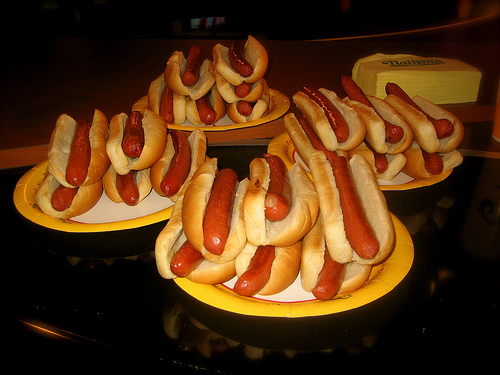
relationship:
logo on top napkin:
[373, 50, 449, 69] [349, 38, 483, 105]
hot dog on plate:
[155, 150, 395, 300] [143, 194, 428, 330]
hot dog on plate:
[103, 108, 165, 178] [143, 194, 428, 330]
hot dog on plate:
[382, 76, 463, 152] [143, 194, 428, 330]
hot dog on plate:
[35, 108, 212, 218] [143, 194, 428, 330]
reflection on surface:
[198, 337, 411, 358] [0, 140, 498, 373]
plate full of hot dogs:
[142, 237, 433, 327] [187, 157, 376, 294]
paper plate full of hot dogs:
[265, 97, 457, 191] [380, 78, 465, 154]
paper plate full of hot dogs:
[265, 97, 457, 191] [337, 69, 414, 155]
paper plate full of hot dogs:
[265, 97, 457, 191] [291, 81, 368, 151]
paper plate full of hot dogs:
[265, 97, 457, 191] [400, 140, 465, 180]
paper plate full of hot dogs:
[265, 97, 457, 191] [346, 140, 408, 181]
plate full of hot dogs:
[133, 102, 287, 133] [182, 162, 379, 275]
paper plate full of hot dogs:
[266, 130, 453, 191] [287, 85, 452, 170]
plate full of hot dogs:
[172, 210, 414, 318] [157, 52, 275, 124]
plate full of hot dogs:
[17, 182, 173, 237] [42, 116, 196, 204]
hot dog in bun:
[155, 150, 395, 300] [180, 157, 248, 264]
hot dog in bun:
[155, 150, 395, 300] [230, 152, 315, 243]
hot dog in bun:
[155, 150, 395, 300] [307, 143, 394, 270]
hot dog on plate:
[235, 141, 332, 239] [305, 262, 412, 319]